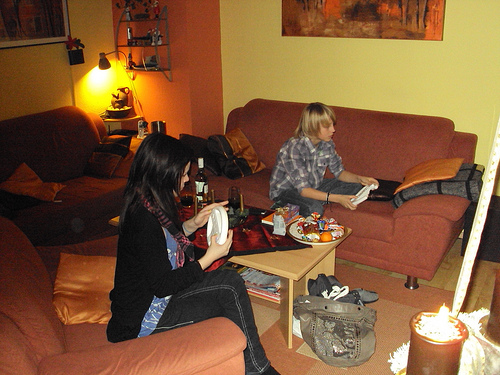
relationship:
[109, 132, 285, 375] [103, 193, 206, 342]
child wearing sweater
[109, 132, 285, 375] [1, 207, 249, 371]
child sitting in chair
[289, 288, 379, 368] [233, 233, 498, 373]
bag on floor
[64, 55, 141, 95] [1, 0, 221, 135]
light shining on wall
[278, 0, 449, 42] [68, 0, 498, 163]
picture hanging on wall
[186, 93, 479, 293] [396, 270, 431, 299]
sofa has leg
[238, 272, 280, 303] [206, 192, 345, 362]
magazines under table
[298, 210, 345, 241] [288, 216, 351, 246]
food on plate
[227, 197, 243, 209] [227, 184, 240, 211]
liquid in glass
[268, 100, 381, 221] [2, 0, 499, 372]
boy in living room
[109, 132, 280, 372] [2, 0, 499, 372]
child in living room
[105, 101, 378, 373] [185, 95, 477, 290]
children sitting on couch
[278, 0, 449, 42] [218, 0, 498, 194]
picture attached to wall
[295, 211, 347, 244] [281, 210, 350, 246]
food on top of teapoy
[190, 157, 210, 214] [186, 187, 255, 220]
bottle on top of teapoy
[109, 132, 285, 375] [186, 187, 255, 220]
child on top of teapoy